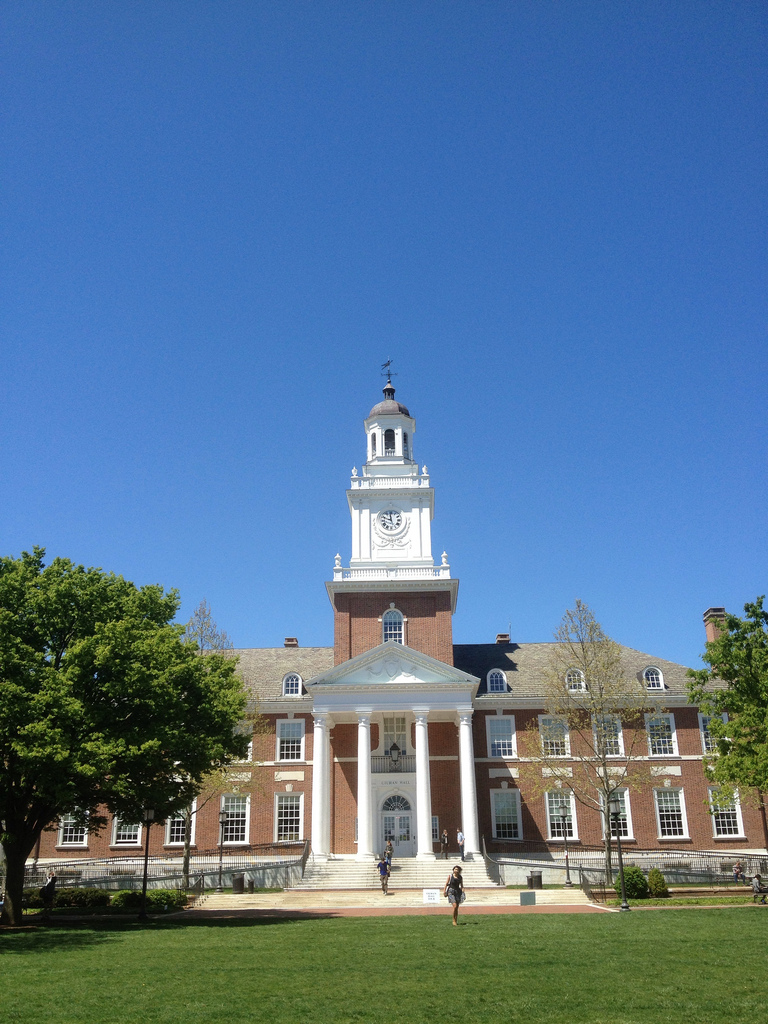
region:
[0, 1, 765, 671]
sky is vivid blue and clear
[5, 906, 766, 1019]
green grass is neatly mowed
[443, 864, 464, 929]
woman is wearing gray shorts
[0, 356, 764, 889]
weather vane on building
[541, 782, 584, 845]
multi-paned window with white trim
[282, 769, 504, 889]
steps leading up to white doorway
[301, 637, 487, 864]
four white columns support the entryway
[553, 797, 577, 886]
light on black metal pole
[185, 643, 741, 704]
roof is brown shingled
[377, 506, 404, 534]
A clock on a tower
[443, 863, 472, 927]
A girl on a lawn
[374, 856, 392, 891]
A person walking up stairs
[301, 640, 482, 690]
A roof on an entry way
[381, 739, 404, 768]
A light over a door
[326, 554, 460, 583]
A balcony below a clock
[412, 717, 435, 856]
A tall white column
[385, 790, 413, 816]
A half circle window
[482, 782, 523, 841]
A tall window on a building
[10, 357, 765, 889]
the building has a lot of windows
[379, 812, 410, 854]
the doors are white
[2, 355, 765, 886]
the stairs in the front of the very large building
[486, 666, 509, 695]
the window is arched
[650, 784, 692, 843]
the window has a white frame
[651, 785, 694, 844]
the window is closed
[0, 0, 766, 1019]
the clear blue sky above the green grass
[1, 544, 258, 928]
the tree is full of green leaves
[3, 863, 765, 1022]
the woman is walking on the lush green grass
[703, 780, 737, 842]
glass window on building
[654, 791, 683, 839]
glass window on building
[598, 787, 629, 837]
glass window on building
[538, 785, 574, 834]
glass window on building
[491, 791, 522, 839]
glass window on building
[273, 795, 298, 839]
glass window on building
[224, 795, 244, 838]
glass window on building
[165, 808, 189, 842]
glass window on building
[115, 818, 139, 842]
glass window on building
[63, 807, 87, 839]
glass window on building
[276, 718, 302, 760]
building has a window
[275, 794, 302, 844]
building has a window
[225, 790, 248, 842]
building has a window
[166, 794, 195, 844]
building has a window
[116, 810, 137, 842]
building has a window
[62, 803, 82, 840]
building has a window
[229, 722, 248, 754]
building has a window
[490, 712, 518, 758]
building has a window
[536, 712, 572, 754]
building has a window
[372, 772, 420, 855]
the white front door of the bulding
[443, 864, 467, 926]
the girl walking on the grass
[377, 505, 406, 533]
the round clock on the tower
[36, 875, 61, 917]
a person under the tree on the left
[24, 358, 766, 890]
the beautiful brick building with a tower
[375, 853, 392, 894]
a man in a blue t-shirt near the stairs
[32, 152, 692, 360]
a sky that is blue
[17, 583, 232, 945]
a tree that is large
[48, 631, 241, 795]
leaves that are green in color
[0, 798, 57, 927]
a trunk that is brown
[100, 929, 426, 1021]
some grass that is green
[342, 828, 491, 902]
some stairs that are white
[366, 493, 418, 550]
a clock that is white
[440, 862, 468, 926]
a person wearing a gray skirt